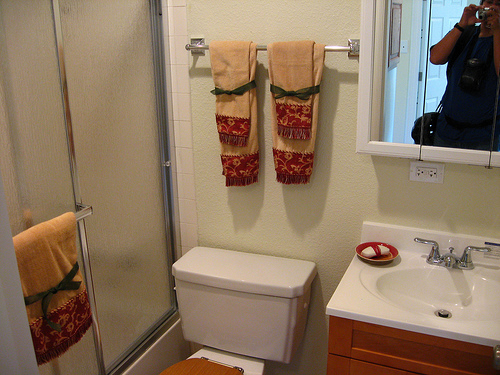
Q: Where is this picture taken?
A: A bathroom.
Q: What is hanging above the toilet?
A: Two towels.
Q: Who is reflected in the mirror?
A: A woman.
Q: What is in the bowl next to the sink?
A: Soap.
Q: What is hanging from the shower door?
A: A towel.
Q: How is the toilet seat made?
A: Of wood.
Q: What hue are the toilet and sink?
A: White.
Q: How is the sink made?
A: Of porcelain.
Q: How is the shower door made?
A: Of glass.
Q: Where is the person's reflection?
A: In the mirror.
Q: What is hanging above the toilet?
A: Towels.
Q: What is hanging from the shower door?
A: Towel.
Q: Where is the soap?
A: On the sink.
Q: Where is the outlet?
A: Under the medicine cabinet.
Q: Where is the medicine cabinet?
A: Above the sink.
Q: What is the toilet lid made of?
A: Wood.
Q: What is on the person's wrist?
A: A watch.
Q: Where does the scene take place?
A: In a bathroom.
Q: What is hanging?
A: Towels.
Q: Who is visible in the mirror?
A: Person taking picture.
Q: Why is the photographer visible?
A: Reflected in mirror.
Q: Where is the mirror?
A: Above the sink.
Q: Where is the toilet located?
A: Between the sink and the shower.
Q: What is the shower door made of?
A: Glass.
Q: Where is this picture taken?
A: Bathroom.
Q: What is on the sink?
A: Soap.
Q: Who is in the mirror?
A: A woman.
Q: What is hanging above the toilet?
A: Hand towels.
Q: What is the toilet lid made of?
A: Wood.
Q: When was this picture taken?
A: Daytime.